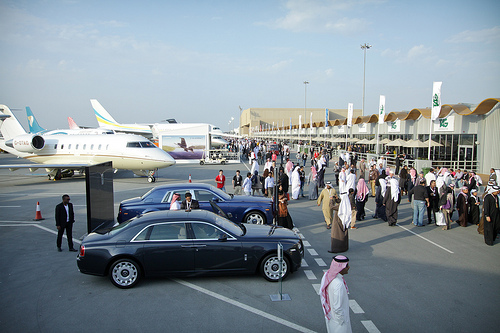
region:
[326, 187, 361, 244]
A person is standing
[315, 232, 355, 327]
A person is standing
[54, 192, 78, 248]
A person is standing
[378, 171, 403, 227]
A person is standing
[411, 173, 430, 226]
A person is standing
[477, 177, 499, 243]
A person is standing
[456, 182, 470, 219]
A person is standing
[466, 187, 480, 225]
A person is standing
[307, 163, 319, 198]
A person is standing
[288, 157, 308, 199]
A person is standing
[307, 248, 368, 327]
man is wearing red cover on head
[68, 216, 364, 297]
car is black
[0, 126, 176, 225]
plane is white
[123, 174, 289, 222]
car is blue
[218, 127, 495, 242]
many people standing in front of building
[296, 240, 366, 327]
man is wearing white clothes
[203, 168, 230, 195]
person's shirt is red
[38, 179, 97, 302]
man has on black suit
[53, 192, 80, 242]
man's shirt is white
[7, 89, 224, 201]
plane is parked on ground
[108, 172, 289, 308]
two parked cars on the road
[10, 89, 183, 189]
white plane on the runway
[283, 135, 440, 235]
group of people standing around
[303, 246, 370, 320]
man in religious clothing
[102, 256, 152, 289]
silver rims on tire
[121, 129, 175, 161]
window on front of plane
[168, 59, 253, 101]
blue sky above airport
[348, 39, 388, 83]
light pole above building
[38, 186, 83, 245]
man in black and white clothes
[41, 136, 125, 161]
windows on side of plane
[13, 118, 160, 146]
A large white plane.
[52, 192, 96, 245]
A man standing behind a car.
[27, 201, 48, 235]
An orange caution cone.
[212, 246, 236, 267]
The car is midnight blue.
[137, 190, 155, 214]
Car is navy blue.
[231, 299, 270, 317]
The lines are white.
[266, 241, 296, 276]
Sign next to the car.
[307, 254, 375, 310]
Man is wearing a turbine.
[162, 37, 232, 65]
The sky is blue.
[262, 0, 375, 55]
Cloud in the sky.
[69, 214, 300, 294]
A black car parked at an airport.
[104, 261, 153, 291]
The back right wheel on a car.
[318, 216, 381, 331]
A man wearing a scarf around his head.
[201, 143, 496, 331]
A crowd of people at an airport.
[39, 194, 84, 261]
A man dressed in a black suit.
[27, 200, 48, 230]
An orange and white cone at an airport.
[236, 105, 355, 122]
A large building at an airport.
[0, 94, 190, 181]
A small jet at an airport.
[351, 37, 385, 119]
A tall tower at an airport.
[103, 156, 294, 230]
A parked car.